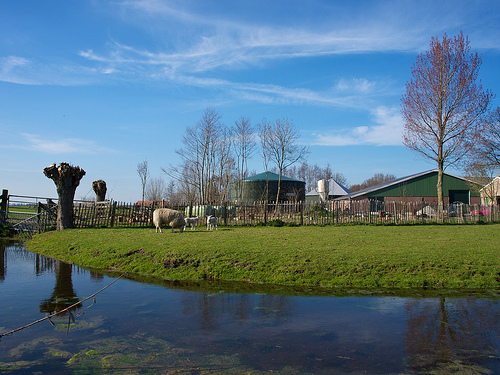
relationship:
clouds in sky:
[2, 2, 500, 156] [0, 1, 499, 204]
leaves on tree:
[404, 27, 497, 163] [399, 27, 495, 222]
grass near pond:
[20, 223, 500, 297] [0, 241, 498, 374]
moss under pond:
[2, 312, 500, 372] [0, 241, 498, 374]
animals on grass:
[153, 208, 219, 234] [20, 223, 500, 297]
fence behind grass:
[5, 194, 499, 229] [20, 223, 500, 297]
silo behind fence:
[238, 170, 307, 212] [5, 194, 499, 229]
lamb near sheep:
[183, 214, 202, 230] [150, 207, 187, 229]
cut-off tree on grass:
[42, 158, 87, 229] [20, 223, 500, 297]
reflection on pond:
[40, 256, 83, 325] [0, 241, 498, 374]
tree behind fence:
[92, 179, 110, 200] [5, 194, 499, 229]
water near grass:
[1, 241, 500, 374] [20, 223, 500, 297]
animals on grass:
[148, 204, 221, 229] [20, 223, 500, 297]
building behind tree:
[335, 167, 487, 218] [399, 27, 495, 222]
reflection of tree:
[38, 256, 83, 317] [44, 163, 87, 228]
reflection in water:
[38, 256, 83, 317] [1, 241, 500, 374]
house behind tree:
[336, 164, 485, 222] [399, 27, 495, 222]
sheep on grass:
[150, 207, 187, 229] [20, 223, 500, 297]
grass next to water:
[20, 223, 500, 297] [1, 241, 500, 374]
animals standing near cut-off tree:
[153, 208, 219, 234] [42, 158, 87, 229]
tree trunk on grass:
[42, 161, 85, 230] [20, 223, 500, 297]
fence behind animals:
[5, 194, 499, 229] [153, 208, 219, 234]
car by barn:
[467, 204, 493, 222] [462, 176, 498, 221]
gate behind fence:
[4, 194, 94, 233] [5, 194, 499, 229]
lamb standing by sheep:
[183, 214, 202, 230] [150, 207, 187, 229]